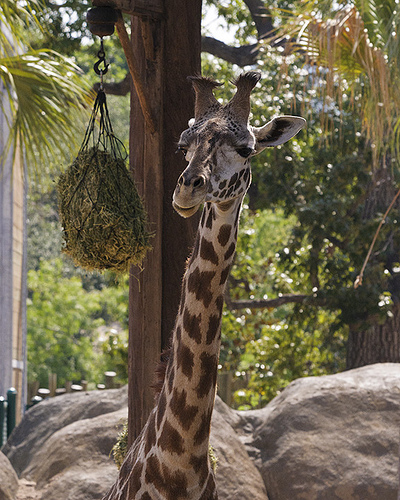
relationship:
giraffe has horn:
[104, 73, 307, 499] [186, 75, 218, 115]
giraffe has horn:
[104, 73, 307, 499] [226, 72, 260, 121]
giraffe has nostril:
[104, 73, 307, 499] [176, 175, 186, 187]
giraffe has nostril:
[104, 73, 307, 499] [193, 177, 204, 190]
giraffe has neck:
[104, 73, 307, 499] [147, 195, 257, 459]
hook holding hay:
[91, 49, 113, 77] [56, 147, 154, 278]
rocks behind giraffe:
[1, 360, 400, 497] [104, 73, 307, 499]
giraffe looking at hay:
[104, 73, 307, 499] [56, 147, 154, 278]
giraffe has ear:
[104, 73, 307, 499] [255, 114, 308, 152]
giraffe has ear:
[104, 73, 307, 499] [185, 117, 197, 127]